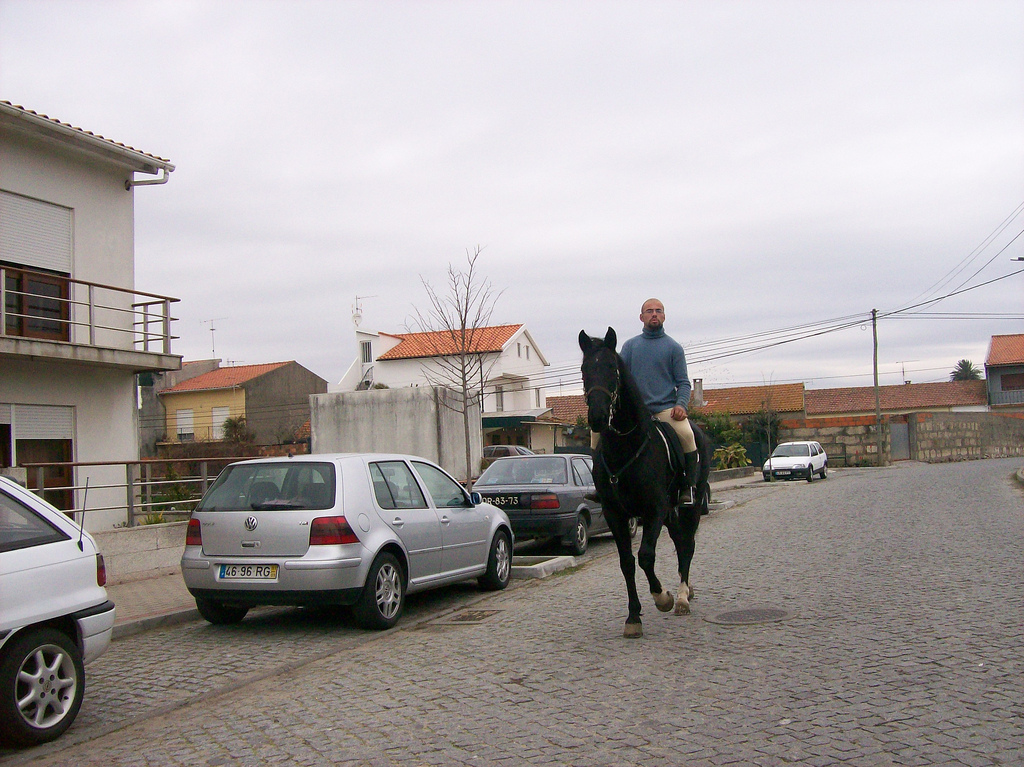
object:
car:
[181, 453, 515, 629]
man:
[583, 299, 698, 508]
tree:
[399, 244, 509, 495]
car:
[762, 441, 827, 482]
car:
[473, 454, 638, 555]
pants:
[654, 405, 700, 455]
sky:
[5, 5, 1023, 391]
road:
[95, 454, 1023, 756]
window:
[212, 407, 231, 440]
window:
[176, 408, 194, 441]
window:
[15, 439, 72, 521]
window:
[0, 265, 71, 342]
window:
[518, 343, 521, 357]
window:
[527, 346, 529, 360]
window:
[536, 389, 540, 407]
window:
[496, 386, 504, 412]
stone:
[808, 435, 835, 443]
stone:
[818, 426, 846, 435]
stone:
[792, 428, 816, 437]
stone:
[846, 445, 866, 454]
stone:
[865, 444, 878, 453]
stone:
[931, 450, 937, 461]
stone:
[909, 420, 917, 460]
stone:
[915, 432, 942, 439]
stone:
[941, 421, 955, 430]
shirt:
[619, 328, 691, 415]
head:
[573, 326, 619, 432]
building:
[328, 323, 552, 483]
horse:
[578, 326, 710, 638]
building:
[156, 360, 329, 458]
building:
[0, 101, 181, 538]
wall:
[781, 406, 1020, 469]